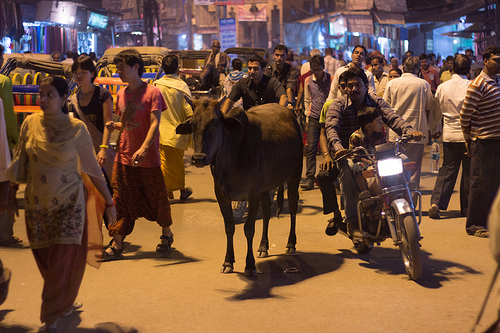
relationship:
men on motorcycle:
[322, 75, 379, 99] [324, 127, 429, 204]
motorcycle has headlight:
[324, 127, 429, 204] [385, 153, 422, 182]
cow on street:
[175, 79, 247, 118] [120, 202, 358, 327]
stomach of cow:
[237, 176, 281, 206] [175, 79, 247, 118]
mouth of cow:
[180, 141, 229, 176] [175, 79, 247, 118]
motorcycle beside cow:
[324, 127, 429, 204] [175, 79, 247, 118]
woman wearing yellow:
[31, 81, 88, 170] [159, 86, 182, 150]